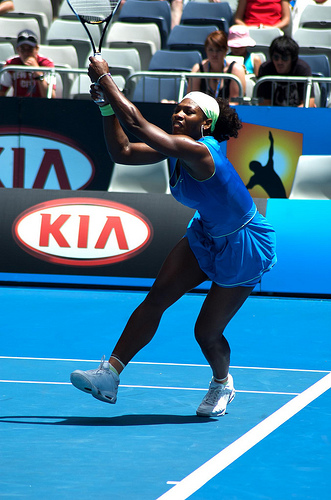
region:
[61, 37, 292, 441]
woman with dark skin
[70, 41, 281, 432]
professional tennis player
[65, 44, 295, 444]
woman wearing blue tennis outfit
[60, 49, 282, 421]
woman wearing white tennis shoes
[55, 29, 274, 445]
woman wearing white and green headband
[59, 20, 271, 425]
woman holding a tennis racket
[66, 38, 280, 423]
woman wearing a blue tank top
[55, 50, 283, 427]
woman wearing a short blue skort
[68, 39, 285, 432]
woman wearing green wristband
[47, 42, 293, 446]
woman playing tennis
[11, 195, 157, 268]
the sign is oval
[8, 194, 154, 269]
the sign is red and white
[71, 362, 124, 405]
her tennis sneaker is white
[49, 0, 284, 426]
the tennis player is readying to hit the ball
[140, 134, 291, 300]
Her tennis dress is shades of blue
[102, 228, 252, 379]
She is wearing leggings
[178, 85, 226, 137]
her hair is wrapped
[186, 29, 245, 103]
spectator is the stands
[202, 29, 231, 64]
her hair is red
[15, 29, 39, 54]
he is wearing a blue hat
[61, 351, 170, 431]
white tennis shoe with left foot flexed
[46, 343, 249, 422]
two feet of a tennis player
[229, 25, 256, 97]
woman in grand stands wearing a pink hat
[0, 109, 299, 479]
blue and white tennis court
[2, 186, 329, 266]
kia advertising sign on back wall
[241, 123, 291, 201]
yellow advertising sign on back wall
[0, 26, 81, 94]
man wearing a red shirt and blue hat is sitting in the grand stands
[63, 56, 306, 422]
tennis player ready to hit the ball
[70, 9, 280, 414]
tennis player wearing a blue skirt and blue shirt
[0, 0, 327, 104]
many spectators sitting in grand stands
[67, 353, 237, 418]
girl wearing white shoes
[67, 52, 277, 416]
girl wearing blue skirt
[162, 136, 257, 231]
girl wearing blue top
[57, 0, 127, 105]
girl holding tennis racket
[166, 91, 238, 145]
girl wearing green headband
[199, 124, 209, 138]
large silver hoop earrings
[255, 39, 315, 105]
boy wearing black sirt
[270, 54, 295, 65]
boy wearing dark sunglasses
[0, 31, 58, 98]
boy wearing red shirt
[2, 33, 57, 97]
boy wearing blue hat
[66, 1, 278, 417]
the woman playing tennis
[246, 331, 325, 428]
the white lines on the ground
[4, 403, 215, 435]
the shadow from the woman on the ground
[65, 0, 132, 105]
the tennis racquet in the woman's hands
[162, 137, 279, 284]
the woman's blue outfit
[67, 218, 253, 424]
the woman's two legs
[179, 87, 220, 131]
the fabric on the woman's head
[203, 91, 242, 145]
the hair on the woman's head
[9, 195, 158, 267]
the KIA logo on the wall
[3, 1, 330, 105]
the spectators in the seat watching the tennis game